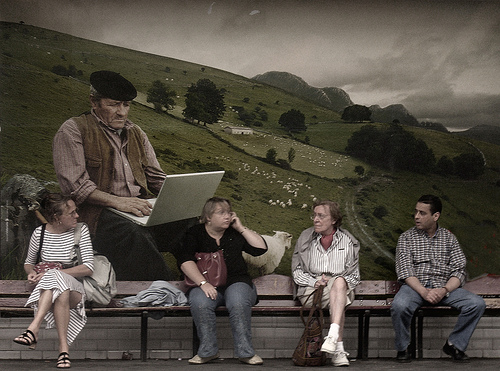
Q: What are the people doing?
A: Sitting on a bench.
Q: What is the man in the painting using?
A: Laptop.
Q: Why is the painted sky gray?
A: Cloudy.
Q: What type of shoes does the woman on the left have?
A: Sandals.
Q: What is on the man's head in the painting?
A: Hat.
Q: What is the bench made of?
A: Wood.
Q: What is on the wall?
A: Picture.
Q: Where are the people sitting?
A: On bench.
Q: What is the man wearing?
A: A plaid shirt.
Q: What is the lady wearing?
A: A striped dress.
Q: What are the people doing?
A: Sitting on a bench.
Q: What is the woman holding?
A: A cell phone.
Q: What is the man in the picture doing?
A: Using a laptop.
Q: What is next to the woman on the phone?
A: A sweatshirt.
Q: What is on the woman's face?
A: Glasses.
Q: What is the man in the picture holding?
A: A laptop.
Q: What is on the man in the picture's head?
A: A black beret.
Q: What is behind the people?
A: A mural.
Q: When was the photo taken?
A: Daytime.